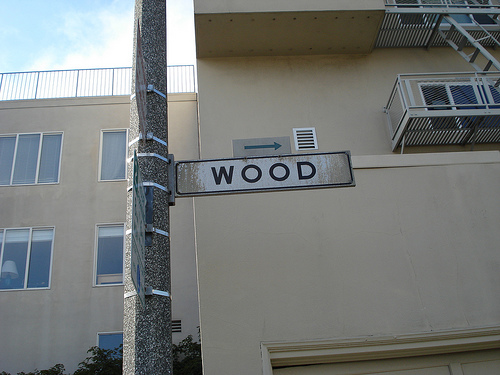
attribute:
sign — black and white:
[149, 123, 361, 208]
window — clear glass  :
[78, 126, 139, 182]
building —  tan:
[215, 207, 445, 324]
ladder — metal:
[434, 6, 488, 85]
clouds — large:
[36, 12, 128, 54]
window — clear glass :
[98, 125, 128, 184]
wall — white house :
[262, 256, 394, 316]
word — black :
[211, 159, 321, 182]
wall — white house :
[193, 149, 498, 373]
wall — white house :
[11, 115, 134, 317]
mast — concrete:
[120, 297, 173, 374]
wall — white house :
[195, 36, 493, 175]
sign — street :
[171, 148, 358, 201]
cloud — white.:
[0, 0, 196, 100]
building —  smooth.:
[36, 10, 498, 371]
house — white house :
[4, 96, 199, 370]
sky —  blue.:
[0, 1, 135, 73]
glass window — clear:
[0, 114, 80, 201]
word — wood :
[207, 157, 317, 189]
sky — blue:
[2, 4, 89, 66]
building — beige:
[3, 0, 488, 367]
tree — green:
[72, 335, 132, 372]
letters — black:
[211, 161, 320, 184]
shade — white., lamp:
[2, 249, 22, 276]